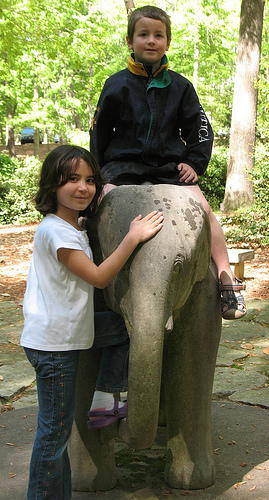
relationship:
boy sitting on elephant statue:
[89, 6, 247, 321] [69, 184, 223, 491]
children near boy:
[21, 143, 163, 498] [89, 6, 247, 321]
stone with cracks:
[2, 301, 268, 499] [214, 385, 268, 410]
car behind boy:
[20, 127, 39, 145] [89, 6, 247, 321]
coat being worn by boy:
[88, 54, 215, 184] [89, 6, 247, 321]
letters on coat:
[199, 105, 209, 145] [88, 54, 215, 184]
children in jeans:
[21, 143, 163, 498] [22, 345, 82, 499]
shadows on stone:
[1, 297, 268, 499] [2, 301, 268, 499]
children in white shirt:
[21, 143, 163, 498] [22, 213, 97, 352]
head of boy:
[126, 4, 173, 62] [89, 6, 247, 321]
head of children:
[37, 146, 103, 219] [21, 143, 163, 498]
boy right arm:
[89, 6, 247, 321] [90, 72, 122, 158]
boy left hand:
[89, 6, 247, 321] [178, 161, 198, 186]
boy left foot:
[89, 6, 247, 321] [219, 284, 248, 318]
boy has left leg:
[89, 6, 247, 321] [179, 185, 235, 287]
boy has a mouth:
[89, 6, 247, 321] [143, 48, 159, 54]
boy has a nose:
[89, 6, 247, 321] [148, 37, 157, 46]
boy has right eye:
[89, 6, 247, 321] [136, 33, 149, 39]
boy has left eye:
[89, 6, 247, 321] [154, 33, 165, 39]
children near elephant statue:
[21, 4, 247, 499] [69, 184, 223, 491]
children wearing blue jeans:
[21, 143, 163, 498] [22, 345, 82, 499]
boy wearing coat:
[89, 6, 247, 321] [88, 54, 215, 184]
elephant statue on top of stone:
[69, 184, 223, 491] [2, 301, 268, 499]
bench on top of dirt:
[227, 247, 258, 279] [2, 223, 268, 301]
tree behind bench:
[220, 0, 265, 209] [227, 247, 258, 279]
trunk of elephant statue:
[120, 295, 167, 453] [69, 184, 223, 491]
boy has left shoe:
[89, 6, 247, 321] [219, 284, 248, 318]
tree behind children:
[220, 0, 265, 209] [21, 4, 247, 499]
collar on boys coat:
[127, 54, 172, 83] [88, 54, 215, 184]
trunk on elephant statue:
[120, 295, 167, 453] [69, 184, 223, 491]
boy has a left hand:
[89, 6, 247, 321] [178, 161, 198, 186]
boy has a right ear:
[89, 6, 247, 321] [124, 35, 132, 48]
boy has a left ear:
[89, 6, 247, 321] [166, 37, 172, 49]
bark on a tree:
[242, 1, 265, 28] [220, 0, 265, 209]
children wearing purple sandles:
[21, 143, 163, 498] [88, 395, 128, 428]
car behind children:
[20, 127, 39, 145] [21, 4, 247, 499]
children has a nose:
[21, 143, 163, 498] [78, 181, 89, 196]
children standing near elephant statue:
[21, 143, 163, 498] [69, 184, 223, 491]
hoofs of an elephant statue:
[68, 455, 219, 492] [69, 184, 223, 491]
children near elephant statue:
[21, 143, 163, 498] [69, 184, 223, 491]